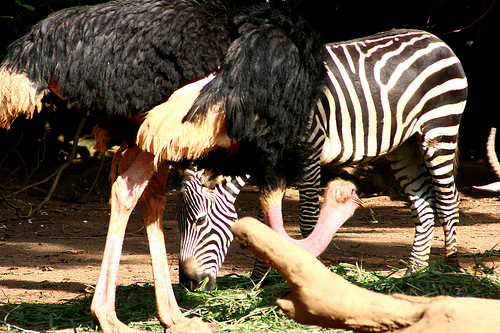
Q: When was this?
A: Daytime.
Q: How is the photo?
A: Clear.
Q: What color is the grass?
A: Green.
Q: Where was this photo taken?
A: In a zoo.